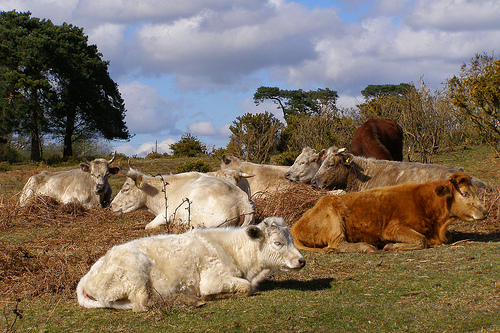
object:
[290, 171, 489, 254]
cow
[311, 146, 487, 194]
cow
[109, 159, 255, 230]
cow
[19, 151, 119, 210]
cow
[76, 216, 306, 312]
cow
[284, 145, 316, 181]
cow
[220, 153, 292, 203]
cow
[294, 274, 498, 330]
grass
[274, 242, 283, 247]
eye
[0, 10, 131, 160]
tree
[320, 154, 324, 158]
tags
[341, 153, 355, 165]
ears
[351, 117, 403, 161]
brown cow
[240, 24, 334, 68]
sky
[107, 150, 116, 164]
horn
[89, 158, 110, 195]
head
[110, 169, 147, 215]
head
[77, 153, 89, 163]
horns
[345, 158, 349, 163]
tag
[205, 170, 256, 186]
cows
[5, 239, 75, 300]
hay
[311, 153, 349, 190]
head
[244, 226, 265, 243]
ear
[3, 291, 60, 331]
ground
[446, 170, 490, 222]
head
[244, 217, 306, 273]
head